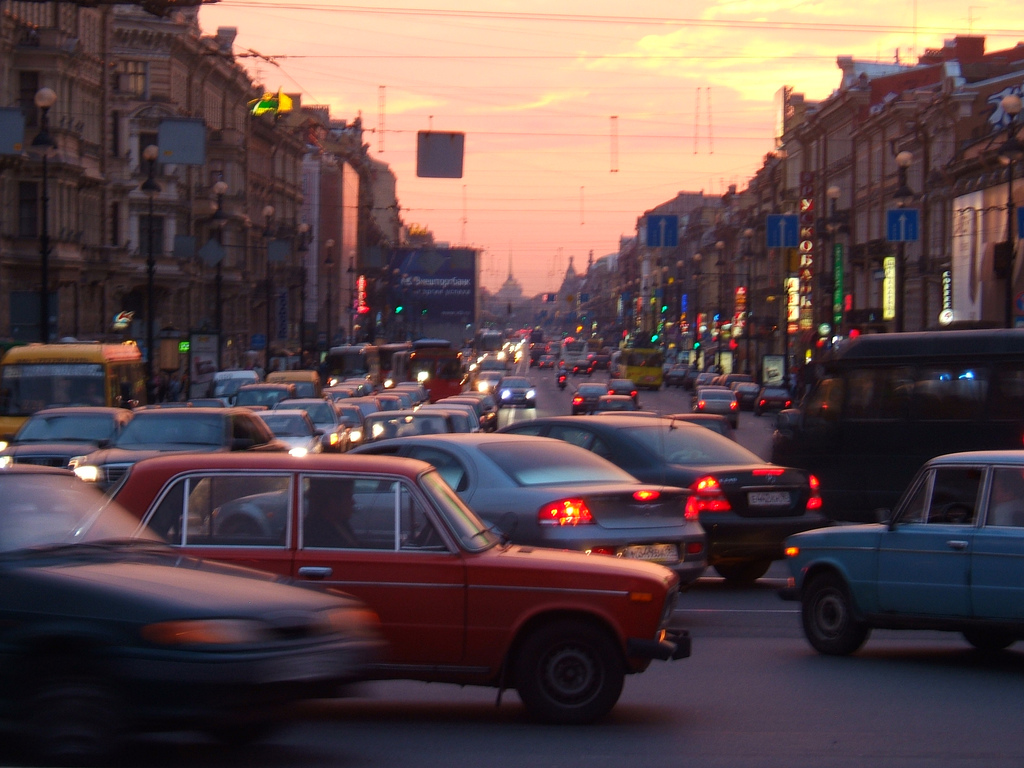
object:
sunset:
[197, 0, 1021, 300]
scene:
[5, 4, 1023, 761]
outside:
[0, 0, 1022, 766]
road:
[0, 325, 1022, 766]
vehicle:
[69, 444, 694, 720]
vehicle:
[198, 424, 710, 595]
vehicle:
[495, 406, 827, 588]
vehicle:
[61, 401, 289, 505]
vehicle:
[233, 388, 334, 462]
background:
[2, 0, 1023, 405]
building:
[2, 0, 312, 397]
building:
[287, 139, 369, 355]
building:
[295, 100, 405, 355]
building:
[745, 27, 1021, 342]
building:
[616, 142, 755, 392]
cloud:
[373, 30, 731, 135]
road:
[262, 325, 1021, 766]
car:
[88, 445, 698, 733]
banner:
[876, 198, 928, 246]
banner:
[751, 208, 806, 256]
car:
[775, 441, 1022, 664]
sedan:
[58, 443, 709, 728]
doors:
[135, 454, 500, 676]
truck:
[0, 336, 151, 442]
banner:
[635, 210, 685, 255]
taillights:
[679, 463, 835, 519]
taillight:
[518, 492, 608, 531]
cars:
[0, 310, 1022, 764]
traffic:
[0, 318, 1016, 763]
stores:
[540, 182, 981, 411]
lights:
[613, 249, 953, 377]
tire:
[495, 598, 635, 734]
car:
[203, 422, 712, 593]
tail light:
[536, 495, 594, 530]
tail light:
[681, 487, 705, 524]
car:
[447, 409, 828, 587]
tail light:
[803, 476, 823, 513]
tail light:
[687, 471, 731, 515]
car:
[469, 410, 834, 584]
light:
[131, 607, 265, 659]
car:
[0, 449, 392, 729]